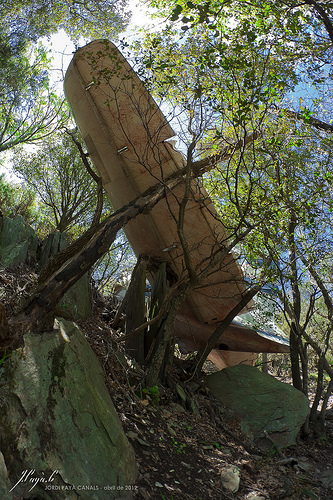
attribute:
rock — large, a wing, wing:
[61, 40, 253, 338]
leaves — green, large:
[202, 364, 310, 459]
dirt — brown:
[2, 244, 329, 499]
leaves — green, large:
[2, 320, 141, 492]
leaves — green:
[37, 230, 97, 321]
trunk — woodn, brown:
[20, 127, 257, 312]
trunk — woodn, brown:
[43, 127, 109, 280]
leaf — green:
[305, 197, 322, 214]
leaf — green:
[308, 166, 320, 185]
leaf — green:
[299, 174, 315, 189]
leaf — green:
[316, 197, 329, 207]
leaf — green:
[293, 177, 307, 185]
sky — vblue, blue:
[2, 1, 329, 321]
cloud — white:
[0, 1, 294, 336]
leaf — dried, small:
[173, 433, 192, 458]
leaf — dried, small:
[204, 440, 234, 463]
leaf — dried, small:
[190, 417, 209, 438]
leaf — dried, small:
[188, 466, 205, 485]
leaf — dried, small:
[154, 454, 173, 477]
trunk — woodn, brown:
[148, 160, 284, 381]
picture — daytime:
[4, 1, 331, 500]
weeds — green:
[138, 252, 186, 287]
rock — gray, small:
[202, 444, 243, 493]